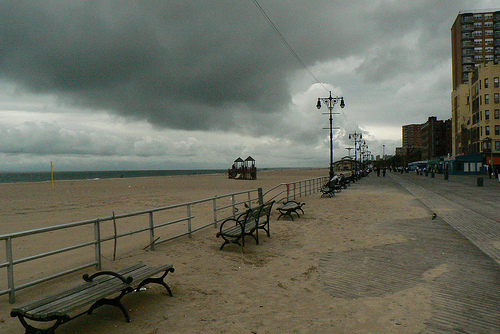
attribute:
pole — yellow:
[41, 160, 58, 187]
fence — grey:
[6, 172, 331, 298]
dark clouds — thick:
[0, 0, 458, 135]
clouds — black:
[1, 0, 498, 145]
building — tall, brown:
[468, 54, 498, 175]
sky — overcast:
[2, 0, 499, 164]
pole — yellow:
[47, 158, 57, 190]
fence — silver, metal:
[27, 201, 202, 259]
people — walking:
[374, 158, 450, 180]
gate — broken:
[100, 212, 157, 264]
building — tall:
[460, 24, 498, 157]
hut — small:
[242, 157, 258, 182]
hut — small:
[226, 155, 245, 182]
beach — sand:
[38, 151, 254, 305]